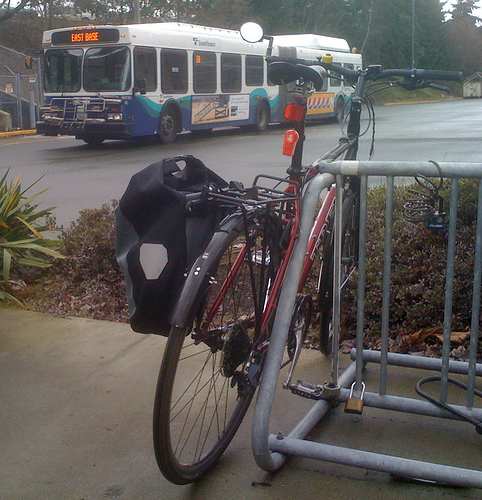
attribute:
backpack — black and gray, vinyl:
[112, 153, 239, 333]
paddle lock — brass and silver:
[351, 377, 382, 420]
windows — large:
[188, 40, 219, 104]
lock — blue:
[391, 158, 442, 224]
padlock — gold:
[343, 376, 369, 415]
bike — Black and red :
[156, 22, 474, 495]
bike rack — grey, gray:
[247, 156, 480, 481]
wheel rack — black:
[211, 166, 298, 336]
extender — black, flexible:
[266, 40, 305, 121]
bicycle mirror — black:
[237, 18, 263, 45]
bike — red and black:
[131, 49, 474, 486]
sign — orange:
[68, 31, 97, 42]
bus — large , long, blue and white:
[33, 10, 362, 144]